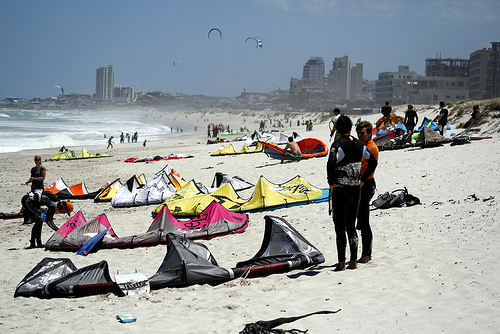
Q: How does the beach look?
A: Occupied.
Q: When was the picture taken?
A: Daytime.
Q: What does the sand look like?
A: White.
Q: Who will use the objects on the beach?
A: No indication.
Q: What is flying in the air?
A: Birds.